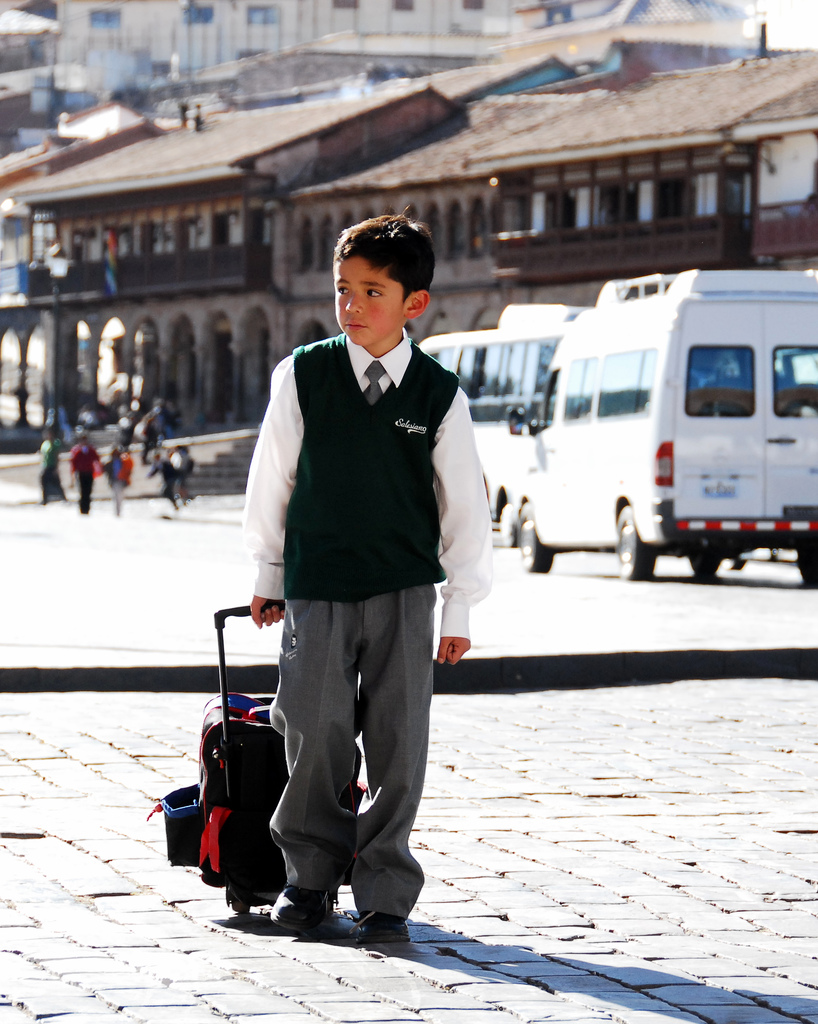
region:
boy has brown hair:
[270, 177, 544, 323]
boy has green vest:
[297, 311, 474, 620]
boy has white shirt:
[229, 338, 481, 618]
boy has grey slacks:
[182, 396, 485, 938]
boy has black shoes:
[265, 857, 433, 953]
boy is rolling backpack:
[176, 578, 311, 927]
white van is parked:
[458, 268, 813, 601]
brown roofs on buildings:
[131, 77, 814, 156]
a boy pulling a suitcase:
[161, 215, 482, 948]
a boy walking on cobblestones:
[199, 207, 543, 985]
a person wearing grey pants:
[280, 583, 437, 926]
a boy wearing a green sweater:
[287, 222, 455, 606]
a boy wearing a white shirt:
[253, 213, 494, 630]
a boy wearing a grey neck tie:
[317, 207, 431, 403]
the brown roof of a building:
[303, 50, 812, 176]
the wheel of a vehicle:
[612, 501, 652, 578]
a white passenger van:
[504, 275, 814, 583]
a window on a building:
[294, 214, 316, 279]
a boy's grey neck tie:
[362, 358, 390, 403]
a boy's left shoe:
[354, 911, 410, 946]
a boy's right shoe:
[270, 887, 328, 933]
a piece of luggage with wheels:
[162, 604, 284, 918]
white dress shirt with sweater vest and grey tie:
[247, 329, 488, 635]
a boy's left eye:
[362, 285, 380, 299]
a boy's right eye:
[335, 281, 350, 295]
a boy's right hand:
[247, 597, 280, 627]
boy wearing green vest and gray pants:
[241, 215, 488, 941]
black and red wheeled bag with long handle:
[158, 598, 336, 915]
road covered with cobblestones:
[2, 690, 817, 1021]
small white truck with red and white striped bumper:
[506, 267, 816, 579]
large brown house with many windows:
[268, 89, 616, 408]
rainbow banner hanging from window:
[100, 227, 119, 300]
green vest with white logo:
[290, 333, 459, 597]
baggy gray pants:
[276, 584, 437, 915]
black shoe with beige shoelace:
[350, 907, 413, 942]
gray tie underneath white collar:
[340, 334, 414, 405]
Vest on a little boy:
[274, 330, 448, 594]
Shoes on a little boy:
[261, 876, 411, 955]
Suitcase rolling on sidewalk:
[162, 693, 297, 919]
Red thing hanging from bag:
[200, 798, 230, 878]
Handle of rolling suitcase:
[208, 598, 281, 732]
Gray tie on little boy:
[360, 357, 389, 410]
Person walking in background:
[97, 446, 133, 521]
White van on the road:
[476, 277, 812, 587]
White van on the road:
[415, 299, 589, 529]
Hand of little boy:
[429, 621, 476, 668]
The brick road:
[4, 687, 813, 1022]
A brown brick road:
[0, 688, 816, 1008]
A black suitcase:
[133, 681, 373, 919]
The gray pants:
[248, 587, 558, 959]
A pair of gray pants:
[251, 589, 483, 945]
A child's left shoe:
[256, 868, 338, 936]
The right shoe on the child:
[339, 900, 423, 950]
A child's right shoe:
[337, 889, 438, 963]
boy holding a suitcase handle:
[154, 140, 547, 987]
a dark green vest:
[249, 328, 468, 616]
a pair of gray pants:
[266, 571, 456, 928]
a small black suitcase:
[179, 700, 302, 896]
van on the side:
[485, 251, 816, 584]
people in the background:
[23, 379, 201, 533]